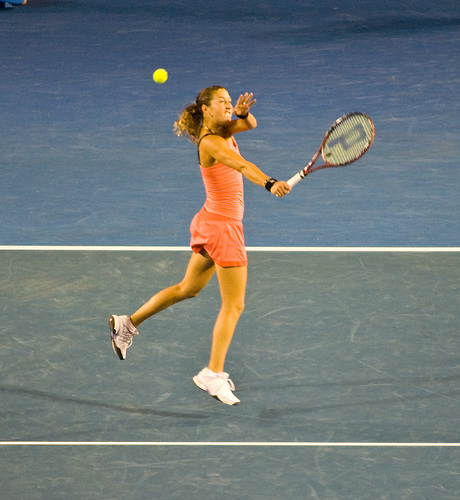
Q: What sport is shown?
A: Tennis.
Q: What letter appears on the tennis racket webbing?
A: P.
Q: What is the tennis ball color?
A: Yellow.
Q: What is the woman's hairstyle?
A: Ponytail.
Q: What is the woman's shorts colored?
A: Orange.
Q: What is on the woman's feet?
A: Sneakers.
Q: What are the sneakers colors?
A: White.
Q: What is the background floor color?
A: Blue.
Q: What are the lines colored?
A: White.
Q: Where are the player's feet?
A: In the air.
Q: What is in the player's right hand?
A: Tennis racket.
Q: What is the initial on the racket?
A: P.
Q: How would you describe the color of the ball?
A: Yellow.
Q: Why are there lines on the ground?
A: Boundary lines.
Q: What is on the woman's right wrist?
A: Wristband.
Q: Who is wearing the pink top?
A: Tennis player.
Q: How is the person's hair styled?
A: Poneytail.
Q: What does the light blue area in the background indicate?
A: Out of bounds.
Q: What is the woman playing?
A: Tennis.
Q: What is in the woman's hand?
A: A tennis racket.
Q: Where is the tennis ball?
A: In the air.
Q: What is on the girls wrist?
A: Black wristbands.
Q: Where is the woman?
A: On a tennis court.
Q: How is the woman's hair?
A: In a ponytail.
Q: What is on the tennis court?
A: White lines.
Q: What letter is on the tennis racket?
A: P.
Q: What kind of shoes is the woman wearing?
A: Tennis shoes.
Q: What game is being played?
A: Tennis.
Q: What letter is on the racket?
A: P.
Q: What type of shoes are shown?
A: Sneakers.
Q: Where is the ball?
A: In the air.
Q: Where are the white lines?
A: Tennis court.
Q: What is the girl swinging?
A: A racket.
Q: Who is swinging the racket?
A: A girl.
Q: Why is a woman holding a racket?
A: To play tennis.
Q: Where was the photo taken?
A: At a tennis court.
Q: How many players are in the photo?
A: One.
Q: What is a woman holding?
A: Tennis racket.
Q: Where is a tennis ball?
A: In the air.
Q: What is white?
A: Lines on the court.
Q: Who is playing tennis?
A: A woman.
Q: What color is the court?
A: Blue.